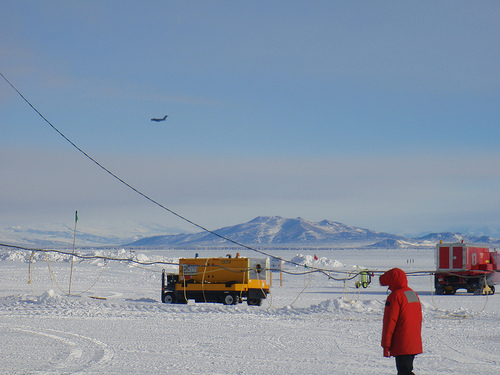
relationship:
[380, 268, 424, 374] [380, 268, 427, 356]
man wearing a coat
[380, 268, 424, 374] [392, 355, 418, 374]
man wearing pants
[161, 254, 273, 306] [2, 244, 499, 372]
truck on snow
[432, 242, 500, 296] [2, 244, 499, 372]
truck on snow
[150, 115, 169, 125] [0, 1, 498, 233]
airplane in sky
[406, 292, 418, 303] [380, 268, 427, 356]
patch on coat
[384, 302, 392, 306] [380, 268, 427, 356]
patch on coat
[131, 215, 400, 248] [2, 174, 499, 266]
mountain in background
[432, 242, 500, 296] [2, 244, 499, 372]
truck in snow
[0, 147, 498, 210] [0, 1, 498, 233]
clouds in sky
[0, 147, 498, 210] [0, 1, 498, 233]
clouds in blue sky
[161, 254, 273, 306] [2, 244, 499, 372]
truck in snow